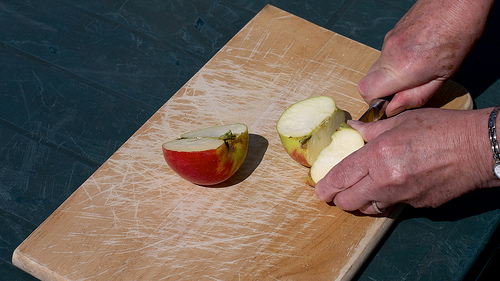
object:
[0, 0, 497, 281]
table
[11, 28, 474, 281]
board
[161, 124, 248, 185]
apple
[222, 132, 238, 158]
stem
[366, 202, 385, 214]
ring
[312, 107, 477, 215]
hand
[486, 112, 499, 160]
watch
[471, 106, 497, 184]
wrist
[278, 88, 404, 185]
cutting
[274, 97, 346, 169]
half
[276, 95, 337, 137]
surface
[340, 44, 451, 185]
hands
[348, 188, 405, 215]
finger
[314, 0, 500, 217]
person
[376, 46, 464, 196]
lady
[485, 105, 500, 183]
watch